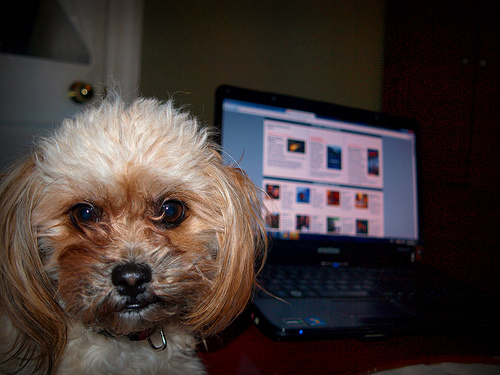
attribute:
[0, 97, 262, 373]
dog — staring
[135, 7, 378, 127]
wall — burgundy